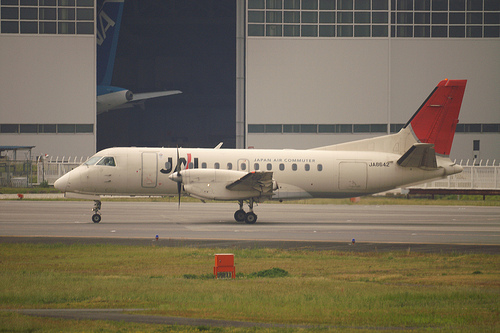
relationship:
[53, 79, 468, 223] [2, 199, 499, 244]
airplane on runway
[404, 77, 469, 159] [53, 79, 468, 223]
tail on airplane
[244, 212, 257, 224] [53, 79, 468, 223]
wheel on airplane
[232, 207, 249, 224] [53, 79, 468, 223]
wheel on airplane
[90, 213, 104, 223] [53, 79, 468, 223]
wheel on airplane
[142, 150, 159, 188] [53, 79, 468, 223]
door aside airplane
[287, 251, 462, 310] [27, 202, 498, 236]
grass next to runway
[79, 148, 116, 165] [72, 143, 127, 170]
windows on cockpit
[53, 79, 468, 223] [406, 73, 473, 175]
airplane has tail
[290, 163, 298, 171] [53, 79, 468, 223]
window on airplane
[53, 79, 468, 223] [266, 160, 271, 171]
airplane has window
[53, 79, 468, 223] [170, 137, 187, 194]
airplane has propeller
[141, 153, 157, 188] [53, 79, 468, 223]
door on a airplane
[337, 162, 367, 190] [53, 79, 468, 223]
cargo door on a airplane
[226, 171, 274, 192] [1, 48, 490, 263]
wing on airplane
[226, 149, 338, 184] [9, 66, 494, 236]
windows on plane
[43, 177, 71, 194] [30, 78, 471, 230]
nose of airplane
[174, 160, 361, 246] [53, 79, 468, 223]
wing of airplane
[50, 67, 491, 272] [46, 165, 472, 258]
airplane on runway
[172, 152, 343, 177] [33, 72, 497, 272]
windows on plane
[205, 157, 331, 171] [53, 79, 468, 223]
windows on airplane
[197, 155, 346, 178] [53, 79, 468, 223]
windows on airplane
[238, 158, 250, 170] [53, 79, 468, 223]
window on airplane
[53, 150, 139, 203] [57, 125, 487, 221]
cockpit of plane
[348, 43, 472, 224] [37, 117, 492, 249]
tail fin of plane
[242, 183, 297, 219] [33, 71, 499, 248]
landing gear on plane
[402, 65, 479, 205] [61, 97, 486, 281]
tail of airplane